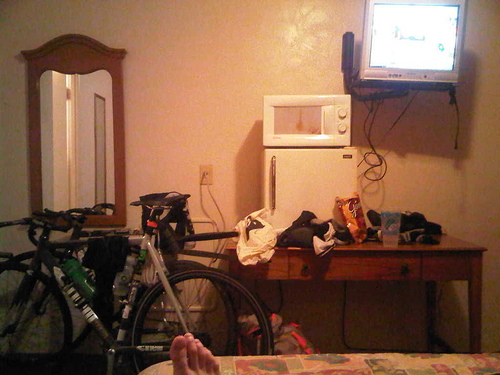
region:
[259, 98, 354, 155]
white microwave on stand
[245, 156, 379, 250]
white fridge with silver handle bar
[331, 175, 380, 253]
red and yellow chips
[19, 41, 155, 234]
mirror with brown frame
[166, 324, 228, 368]
man's foot on bed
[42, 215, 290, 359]
two bikes next to each other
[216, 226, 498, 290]
wood designed desk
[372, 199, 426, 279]
a blue and clear cup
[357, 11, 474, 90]
a silver tv on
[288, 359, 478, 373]
floral comforter on bed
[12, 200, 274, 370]
the bikes standing in the room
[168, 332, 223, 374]
the toes of someone on the bed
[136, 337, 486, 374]
the edge of the bed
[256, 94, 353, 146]
the white microwave on the small refridgerator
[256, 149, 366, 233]
the small white refridgerator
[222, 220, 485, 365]
the wooden table along the wall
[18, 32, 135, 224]
the mirror hanging on the wall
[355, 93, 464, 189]
the wires under the television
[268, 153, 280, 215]
the metal handle on the refridgerator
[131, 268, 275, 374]
the wheel at the back of the bike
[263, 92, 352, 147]
A white microwave oven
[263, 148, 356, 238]
A white mini refrigerator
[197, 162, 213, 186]
A wall socket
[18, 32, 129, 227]
A wood framed wall mirror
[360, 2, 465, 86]
Grey television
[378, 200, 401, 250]
A tall plastic cup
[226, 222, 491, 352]
A wood table with two knobs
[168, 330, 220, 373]
Part of a persons foot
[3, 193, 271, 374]
Two bicycles side by side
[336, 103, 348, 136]
Two round white knobs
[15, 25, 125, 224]
a mirror hanging on a wall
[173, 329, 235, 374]
a person's toes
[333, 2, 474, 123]
a tv mounted on a wall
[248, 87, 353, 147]
a small white microwave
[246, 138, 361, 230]
a small white refrigerator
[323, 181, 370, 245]
a open bag of chips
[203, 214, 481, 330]
a wooden table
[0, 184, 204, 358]
a bike parked inside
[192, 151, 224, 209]
white electrical outlet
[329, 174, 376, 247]
opened bag of chips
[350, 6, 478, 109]
television hanging on the wall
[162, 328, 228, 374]
top of someone's foot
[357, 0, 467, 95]
television is on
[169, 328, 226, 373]
big toe is not the longest toe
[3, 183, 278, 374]
bikes leaning against the wall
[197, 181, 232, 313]
wire hanging down from the wall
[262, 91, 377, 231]
small white microwave on top of a mini fridge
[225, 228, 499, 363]
brown wooden desk pushed up agasint the wall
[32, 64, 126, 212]
reflection in the mirror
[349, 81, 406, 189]
black cords hanging down from the television